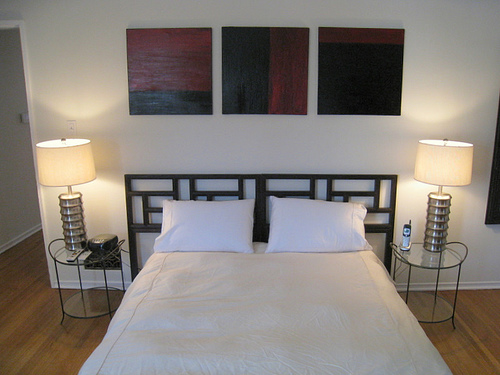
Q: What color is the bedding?
A: White.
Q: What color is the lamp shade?
A: Tan.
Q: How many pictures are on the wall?
A: Three.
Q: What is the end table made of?
A: Glass and metal.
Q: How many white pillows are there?
A: Two.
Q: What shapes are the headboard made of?
A: Rectangles.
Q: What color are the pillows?
A: White.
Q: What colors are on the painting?
A: Red and Black.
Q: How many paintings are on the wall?
A: 3.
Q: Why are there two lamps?
A: For light.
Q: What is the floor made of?
A: Wood.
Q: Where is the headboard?
A: By the wall.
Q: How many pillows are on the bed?
A: 2.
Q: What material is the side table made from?
A: Glass and metal.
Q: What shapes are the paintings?
A: Square.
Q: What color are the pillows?
A: White.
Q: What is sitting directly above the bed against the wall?
A: The headboard.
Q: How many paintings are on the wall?
A: Three.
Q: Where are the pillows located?
A: The head of the bed.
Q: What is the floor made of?
A: Wood.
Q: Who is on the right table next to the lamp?
A: A telephone.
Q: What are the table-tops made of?
A: Glass.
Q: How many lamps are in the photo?
A: Two.